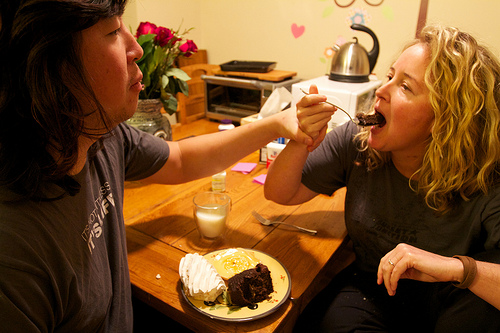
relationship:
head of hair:
[353, 24, 500, 217] [415, 23, 497, 203]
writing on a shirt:
[76, 178, 131, 249] [12, 119, 184, 331]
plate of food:
[172, 243, 309, 320] [178, 244, 274, 313]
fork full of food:
[295, 81, 379, 131] [353, 114, 383, 127]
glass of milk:
[190, 192, 235, 240] [195, 209, 230, 236]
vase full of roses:
[131, 24, 190, 141] [137, 21, 202, 58]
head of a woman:
[371, 15, 499, 217] [264, 26, 500, 333]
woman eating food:
[264, 26, 500, 333] [351, 99, 392, 124]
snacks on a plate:
[228, 260, 277, 318] [178, 247, 291, 323]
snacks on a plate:
[178, 246, 274, 309] [178, 247, 291, 323]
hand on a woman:
[294, 83, 346, 145] [264, 26, 500, 333]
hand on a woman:
[376, 242, 456, 297] [264, 26, 500, 333]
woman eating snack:
[264, 26, 500, 333] [226, 257, 291, 309]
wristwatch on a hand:
[446, 245, 484, 291] [376, 242, 456, 297]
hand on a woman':
[294, 83, 338, 140] [253, 17, 494, 331]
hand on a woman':
[376, 242, 456, 297] [253, 17, 494, 331]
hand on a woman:
[371, 242, 465, 309] [264, 26, 500, 333]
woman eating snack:
[264, 26, 500, 333] [229, 259, 283, 306]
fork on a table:
[251, 211, 318, 235] [122, 111, 358, 331]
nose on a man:
[373, 79, 402, 104] [0, 0, 327, 333]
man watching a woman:
[0, 0, 327, 333] [264, 26, 500, 333]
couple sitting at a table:
[3, 2, 492, 307] [115, 90, 376, 331]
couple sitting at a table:
[0, 0, 500, 333] [115, 90, 376, 331]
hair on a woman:
[351, 24, 499, 216] [264, 26, 500, 333]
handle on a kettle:
[349, 17, 387, 51] [331, 17, 389, 86]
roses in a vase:
[129, 12, 197, 58] [131, 91, 167, 143]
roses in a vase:
[129, 12, 199, 115] [131, 91, 167, 143]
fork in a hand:
[299, 87, 380, 126] [294, 83, 346, 145]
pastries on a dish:
[222, 262, 283, 312] [178, 244, 296, 320]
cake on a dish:
[179, 249, 274, 306] [178, 244, 296, 320]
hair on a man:
[0, 2, 129, 205] [0, 24, 202, 330]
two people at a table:
[0, 40, 497, 328] [111, 120, 351, 330]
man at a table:
[0, 0, 327, 333] [111, 120, 351, 330]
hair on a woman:
[359, 28, 497, 206] [417, 13, 497, 222]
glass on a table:
[190, 192, 235, 240] [108, 104, 368, 331]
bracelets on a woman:
[451, 254, 476, 290] [264, 26, 500, 333]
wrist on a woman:
[282, 122, 318, 167] [264, 26, 500, 333]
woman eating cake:
[417, 13, 497, 222] [224, 260, 284, 312]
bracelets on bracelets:
[455, 238, 481, 287] [451, 254, 476, 290]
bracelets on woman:
[451, 254, 476, 290] [264, 26, 500, 333]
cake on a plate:
[227, 265, 276, 303] [180, 255, 302, 333]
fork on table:
[250, 207, 320, 243] [125, 224, 155, 284]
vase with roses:
[123, 98, 171, 143] [159, 52, 179, 90]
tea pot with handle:
[325, 16, 386, 95] [360, 51, 380, 101]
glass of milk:
[190, 192, 235, 240] [182, 187, 239, 244]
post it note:
[230, 133, 264, 204] [233, 158, 253, 175]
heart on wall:
[286, 18, 310, 42] [258, 50, 287, 64]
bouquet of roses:
[142, 50, 205, 100] [129, 12, 197, 58]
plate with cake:
[178, 247, 291, 323] [179, 249, 274, 306]